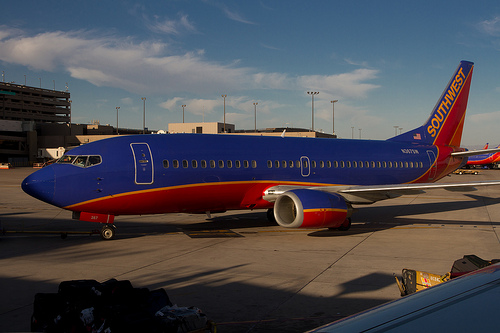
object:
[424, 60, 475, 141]
tail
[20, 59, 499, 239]
plane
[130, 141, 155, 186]
door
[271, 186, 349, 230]
engine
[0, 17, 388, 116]
clouds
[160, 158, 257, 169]
windows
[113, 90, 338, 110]
lights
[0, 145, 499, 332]
airport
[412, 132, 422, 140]
flag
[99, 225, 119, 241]
wheels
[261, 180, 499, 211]
wing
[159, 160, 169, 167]
window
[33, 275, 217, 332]
luggage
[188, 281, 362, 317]
shade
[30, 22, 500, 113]
sky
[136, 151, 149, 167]
part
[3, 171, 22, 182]
part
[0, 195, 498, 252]
runway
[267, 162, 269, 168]
section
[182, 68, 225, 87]
part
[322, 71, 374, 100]
cloud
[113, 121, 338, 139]
building